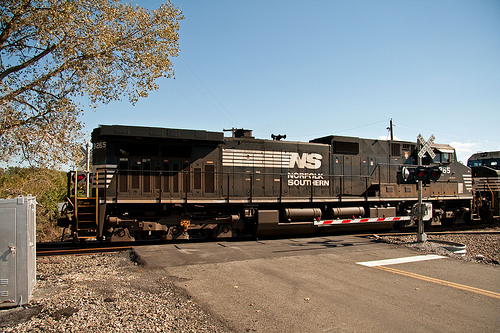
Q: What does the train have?
A: White letters.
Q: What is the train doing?
A: Not moving.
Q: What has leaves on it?
A: The tree.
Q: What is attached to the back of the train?
A: Yellow stairs.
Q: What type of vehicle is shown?
A: Train.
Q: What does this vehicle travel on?
A: Tracks.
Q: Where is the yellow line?
A: Middle of road.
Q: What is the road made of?
A: Asphalt.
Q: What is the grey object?
A: Power box.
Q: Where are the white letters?
A: On train.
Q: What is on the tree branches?
A: Leaves.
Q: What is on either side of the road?
A: Gravel.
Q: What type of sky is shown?
A: Clear.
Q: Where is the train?
A: On the tracks.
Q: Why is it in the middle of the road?
A: Crossing.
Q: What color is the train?
A: Black.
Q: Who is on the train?
A: Conductor.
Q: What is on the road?
A: The train.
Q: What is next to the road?
A: Trees.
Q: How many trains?
A: 1.